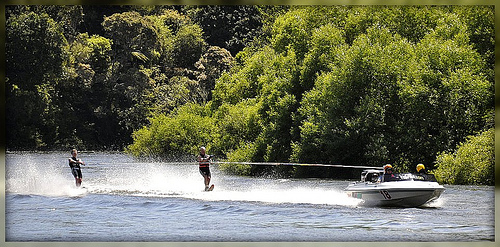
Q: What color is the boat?
A: White.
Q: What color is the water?
A: Blue.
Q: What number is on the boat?
A: 18.